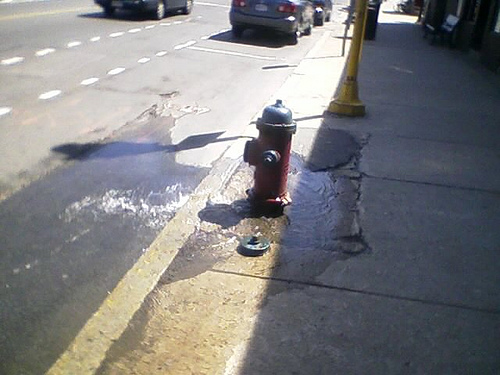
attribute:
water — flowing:
[0, 98, 217, 374]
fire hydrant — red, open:
[240, 100, 298, 216]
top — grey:
[256, 98, 297, 134]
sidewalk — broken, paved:
[43, 4, 495, 374]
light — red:
[276, 4, 296, 14]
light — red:
[226, 0, 246, 8]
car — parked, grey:
[228, 0, 314, 46]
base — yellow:
[330, 77, 390, 116]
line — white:
[184, 48, 292, 73]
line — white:
[2, 14, 260, 119]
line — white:
[128, 25, 145, 34]